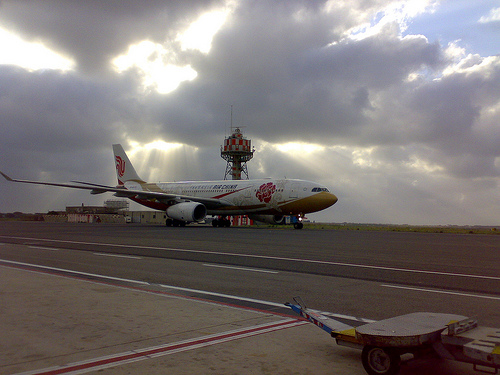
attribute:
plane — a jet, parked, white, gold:
[0, 146, 342, 230]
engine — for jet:
[173, 187, 239, 224]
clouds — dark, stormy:
[157, 18, 487, 148]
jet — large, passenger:
[3, 142, 338, 227]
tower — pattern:
[206, 122, 267, 175]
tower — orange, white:
[220, 124, 254, 177]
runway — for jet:
[284, 252, 498, 274]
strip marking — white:
[2, 234, 499, 280]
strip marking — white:
[26, 243, 60, 251]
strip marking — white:
[92, 250, 142, 259]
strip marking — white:
[201, 261, 278, 273]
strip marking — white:
[379, 282, 499, 300]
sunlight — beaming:
[104, 95, 336, 180]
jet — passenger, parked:
[5, 114, 345, 239]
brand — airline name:
[255, 181, 277, 204]